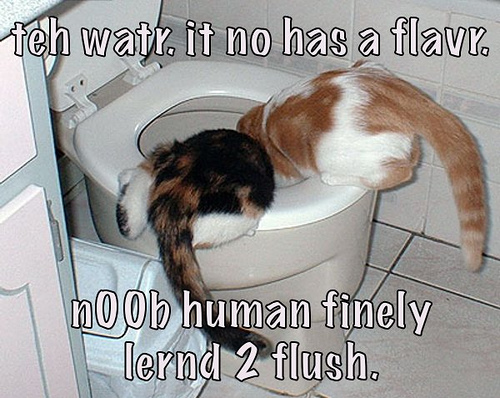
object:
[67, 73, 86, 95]
pieces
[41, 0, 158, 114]
bowl lid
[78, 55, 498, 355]
cat's heads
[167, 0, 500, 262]
wall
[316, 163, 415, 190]
paws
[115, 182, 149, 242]
paw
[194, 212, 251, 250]
paw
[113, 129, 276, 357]
cat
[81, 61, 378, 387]
toilet bowl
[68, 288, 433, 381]
letters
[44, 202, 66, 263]
door hinges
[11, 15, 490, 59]
letters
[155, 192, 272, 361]
cat tail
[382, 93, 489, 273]
cat tail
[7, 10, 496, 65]
words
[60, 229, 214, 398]
trash can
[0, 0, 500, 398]
bathroom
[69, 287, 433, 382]
words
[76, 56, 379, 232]
bowl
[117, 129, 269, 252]
body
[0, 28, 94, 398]
door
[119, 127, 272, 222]
back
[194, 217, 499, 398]
bathroom floor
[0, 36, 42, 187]
drawer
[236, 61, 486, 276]
cat